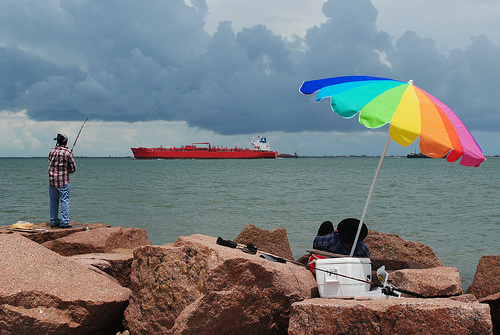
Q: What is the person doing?
A: Fishing.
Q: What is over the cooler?
A: A rainbow colored umbrella.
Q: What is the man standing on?
A: Large ragged rocks.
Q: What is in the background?
A: A large red ship.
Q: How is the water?
A: It's calm.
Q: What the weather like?
A: Cloudy and a little dark.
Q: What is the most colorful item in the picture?
A: Umbrella.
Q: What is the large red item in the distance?
A: Boat.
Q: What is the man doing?
A: FIshing.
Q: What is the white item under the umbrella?
A: Cooler.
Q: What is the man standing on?
A: Rocks.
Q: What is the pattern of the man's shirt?
A: Plaid.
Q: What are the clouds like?
A: Puffy.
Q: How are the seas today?
A: Calm.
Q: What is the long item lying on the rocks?
A: A fishing pole.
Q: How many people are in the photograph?
A: Two.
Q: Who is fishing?
A: The person that is standing.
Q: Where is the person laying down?
A: Under the umbrella.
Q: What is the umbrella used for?
A: For shade.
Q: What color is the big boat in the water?
A: Red.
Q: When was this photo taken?
A: During the daytime.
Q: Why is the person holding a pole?
A: He is fishing.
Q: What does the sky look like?
A: Mostly cloudy.